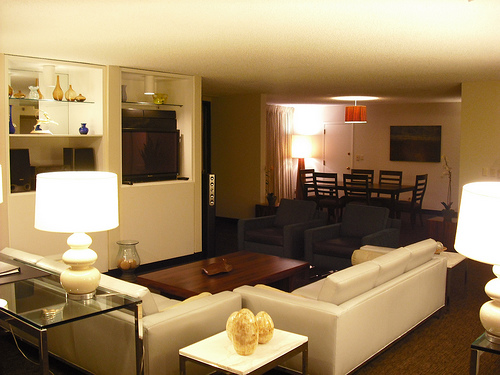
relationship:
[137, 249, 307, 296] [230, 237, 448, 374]
table next to sofa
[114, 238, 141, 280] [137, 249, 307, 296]
vase next to table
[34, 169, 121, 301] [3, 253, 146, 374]
lamp on table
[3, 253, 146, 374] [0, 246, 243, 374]
table behind sofa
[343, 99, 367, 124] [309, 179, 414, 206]
light above dining table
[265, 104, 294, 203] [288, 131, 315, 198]
curtain next to light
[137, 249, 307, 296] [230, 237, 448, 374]
table in front of sofa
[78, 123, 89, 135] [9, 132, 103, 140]
vase on shelf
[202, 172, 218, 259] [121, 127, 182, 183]
speaker next to television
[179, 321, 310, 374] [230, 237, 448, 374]
end table next to sofa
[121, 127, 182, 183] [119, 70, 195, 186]
television in entertainment center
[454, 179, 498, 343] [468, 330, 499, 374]
lamp on table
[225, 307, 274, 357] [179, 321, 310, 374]
sculpture on end table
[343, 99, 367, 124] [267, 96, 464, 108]
light on ceiling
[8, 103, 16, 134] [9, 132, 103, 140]
bottle on shelf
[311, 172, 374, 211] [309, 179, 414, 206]
chairs around dining table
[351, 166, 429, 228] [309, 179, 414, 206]
chairs around dining table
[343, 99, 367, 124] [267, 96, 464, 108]
light hanging from ceiling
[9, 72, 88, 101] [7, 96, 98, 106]
bottles on shelf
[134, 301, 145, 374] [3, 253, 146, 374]
leg on table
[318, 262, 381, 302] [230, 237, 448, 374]
cushion on sofa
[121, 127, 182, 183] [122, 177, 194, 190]
television on shelf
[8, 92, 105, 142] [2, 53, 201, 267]
shelves built into wall